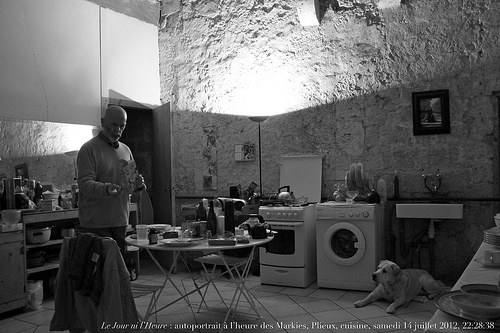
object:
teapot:
[277, 185, 296, 204]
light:
[216, 71, 295, 115]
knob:
[362, 211, 369, 219]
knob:
[355, 212, 360, 218]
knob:
[348, 212, 353, 217]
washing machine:
[314, 197, 380, 290]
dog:
[350, 260, 453, 315]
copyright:
[96, 319, 498, 331]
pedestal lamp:
[248, 116, 269, 199]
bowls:
[449, 292, 499, 319]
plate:
[433, 290, 499, 326]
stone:
[257, 204, 315, 289]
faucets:
[421, 173, 442, 199]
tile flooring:
[251, 282, 348, 332]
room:
[0, 0, 500, 333]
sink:
[396, 202, 464, 220]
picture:
[411, 88, 451, 137]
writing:
[101, 320, 494, 331]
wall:
[3, 3, 170, 197]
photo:
[0, 0, 500, 333]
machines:
[315, 200, 384, 291]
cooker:
[188, 107, 325, 293]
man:
[76, 106, 147, 263]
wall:
[157, 3, 498, 303]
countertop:
[421, 219, 500, 332]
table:
[123, 223, 278, 331]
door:
[151, 101, 178, 274]